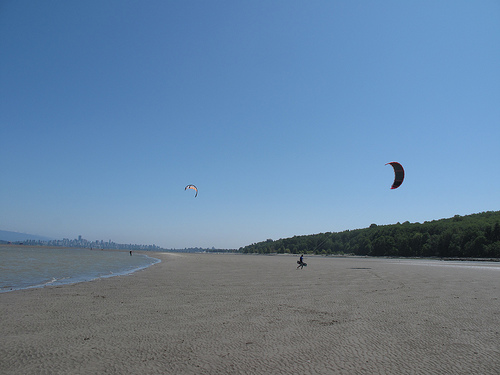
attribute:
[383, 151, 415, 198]
kite — flying, red, black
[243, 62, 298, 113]
sky — blue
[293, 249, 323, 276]
person — walking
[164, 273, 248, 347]
beach — sandy, brown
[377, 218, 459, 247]
trees — green, far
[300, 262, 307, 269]
surboard — dark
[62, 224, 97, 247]
city — far